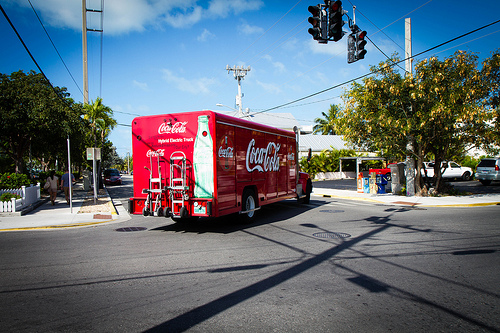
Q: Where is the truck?
A: In the Street.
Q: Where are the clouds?
A: In the sky.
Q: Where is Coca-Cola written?
A: On the truck.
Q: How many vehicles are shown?
A: Five.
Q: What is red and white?
A: The truck.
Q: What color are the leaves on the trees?
A: Green.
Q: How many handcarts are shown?
A: Two.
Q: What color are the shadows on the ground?
A: Black.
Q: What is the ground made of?
A: Concrete.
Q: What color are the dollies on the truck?
A: Silver.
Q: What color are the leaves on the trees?
A: Green.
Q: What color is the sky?
A: Blue.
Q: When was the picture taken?
A: Daytime.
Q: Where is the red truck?
A: In the street.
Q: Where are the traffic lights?
A: Hanging over the street.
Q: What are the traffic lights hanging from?
A: Wires.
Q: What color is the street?
A: Gray.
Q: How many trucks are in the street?
A: One.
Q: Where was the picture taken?
A: On a street corner.